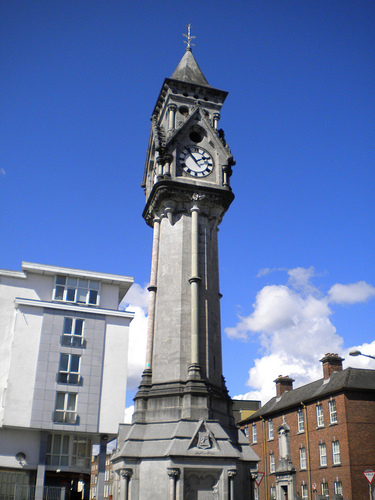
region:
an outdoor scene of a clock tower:
[0, 0, 374, 498]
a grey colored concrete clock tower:
[110, 23, 258, 499]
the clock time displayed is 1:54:
[178, 144, 214, 178]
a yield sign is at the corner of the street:
[362, 468, 374, 483]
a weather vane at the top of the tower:
[181, 24, 197, 51]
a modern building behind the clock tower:
[0, 260, 135, 499]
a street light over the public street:
[348, 350, 373, 360]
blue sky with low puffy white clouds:
[235, 0, 374, 348]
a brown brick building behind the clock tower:
[238, 353, 373, 498]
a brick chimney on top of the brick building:
[319, 352, 345, 378]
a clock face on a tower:
[97, 6, 289, 300]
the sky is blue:
[296, 212, 350, 241]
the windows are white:
[304, 442, 369, 481]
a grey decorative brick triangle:
[160, 409, 266, 472]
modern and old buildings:
[76, 296, 307, 439]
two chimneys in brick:
[253, 334, 373, 390]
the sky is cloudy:
[254, 299, 372, 379]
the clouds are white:
[245, 287, 339, 370]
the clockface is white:
[109, 12, 297, 255]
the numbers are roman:
[121, 72, 285, 267]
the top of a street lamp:
[344, 341, 374, 364]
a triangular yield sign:
[361, 463, 373, 498]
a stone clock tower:
[94, 3, 263, 498]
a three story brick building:
[243, 339, 371, 498]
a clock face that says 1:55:
[178, 143, 219, 180]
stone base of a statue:
[106, 194, 271, 498]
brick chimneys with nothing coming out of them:
[260, 349, 355, 395]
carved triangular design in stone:
[183, 413, 220, 456]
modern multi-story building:
[4, 252, 138, 498]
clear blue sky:
[0, 1, 141, 260]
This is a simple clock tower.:
[114, 18, 267, 463]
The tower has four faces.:
[114, 82, 245, 216]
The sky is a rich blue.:
[241, 12, 370, 224]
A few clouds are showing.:
[238, 233, 366, 343]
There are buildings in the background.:
[7, 242, 117, 467]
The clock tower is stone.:
[104, 71, 266, 481]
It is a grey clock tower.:
[107, 75, 266, 485]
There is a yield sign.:
[338, 454, 373, 498]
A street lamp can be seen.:
[337, 337, 373, 383]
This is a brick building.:
[249, 402, 372, 497]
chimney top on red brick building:
[271, 375, 291, 387]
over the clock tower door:
[183, 410, 217, 452]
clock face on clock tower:
[176, 142, 212, 175]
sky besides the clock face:
[256, 158, 319, 194]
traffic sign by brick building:
[360, 466, 371, 496]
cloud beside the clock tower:
[261, 280, 307, 321]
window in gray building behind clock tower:
[50, 385, 75, 425]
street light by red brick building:
[345, 341, 371, 361]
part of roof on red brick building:
[291, 386, 306, 394]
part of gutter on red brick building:
[304, 432, 310, 443]